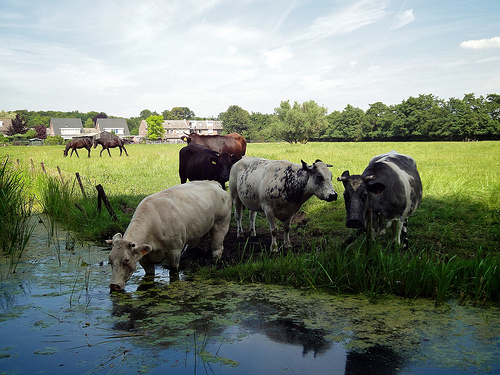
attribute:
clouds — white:
[128, 6, 278, 74]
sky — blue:
[2, 2, 497, 89]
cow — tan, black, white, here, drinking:
[101, 176, 236, 293]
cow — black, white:
[335, 147, 425, 252]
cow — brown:
[178, 127, 250, 163]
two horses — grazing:
[59, 132, 130, 161]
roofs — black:
[50, 113, 133, 133]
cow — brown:
[219, 127, 249, 155]